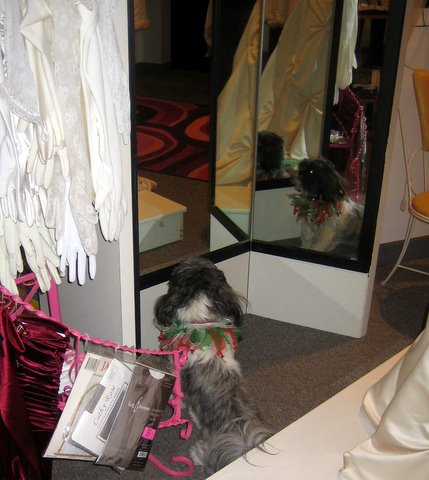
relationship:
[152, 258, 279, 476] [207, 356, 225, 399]
dog has fur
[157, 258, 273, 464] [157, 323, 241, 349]
dog has collar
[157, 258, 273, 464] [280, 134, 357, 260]
dog has reflection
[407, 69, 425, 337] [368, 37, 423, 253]
chair near wall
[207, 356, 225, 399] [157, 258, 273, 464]
fur on dog